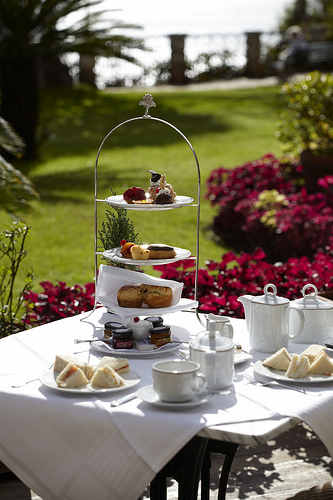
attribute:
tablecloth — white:
[0, 307, 332, 498]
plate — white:
[106, 194, 193, 212]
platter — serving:
[42, 357, 146, 399]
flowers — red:
[23, 150, 331, 321]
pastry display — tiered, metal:
[87, 89, 203, 363]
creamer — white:
[187, 297, 245, 347]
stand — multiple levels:
[91, 91, 200, 334]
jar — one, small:
[144, 316, 163, 325]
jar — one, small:
[149, 325, 170, 346]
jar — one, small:
[111, 327, 135, 349]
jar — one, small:
[104, 321, 124, 342]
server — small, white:
[203, 312, 233, 336]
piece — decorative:
[137, 92, 154, 107]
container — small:
[127, 319, 152, 338]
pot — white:
[244, 268, 332, 357]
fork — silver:
[263, 380, 320, 397]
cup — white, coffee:
[143, 355, 206, 403]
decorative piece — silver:
[138, 93, 155, 115]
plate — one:
[88, 335, 173, 356]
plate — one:
[98, 295, 194, 313]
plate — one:
[102, 244, 190, 266]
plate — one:
[104, 191, 193, 211]